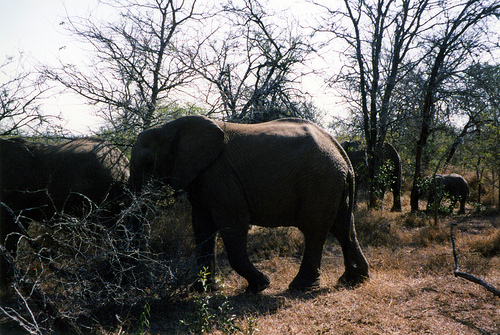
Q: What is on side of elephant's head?
A: Large ear.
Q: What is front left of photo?
A: Bare branches.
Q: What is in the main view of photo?
A: Elephant.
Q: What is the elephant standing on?
A: Patch of ground.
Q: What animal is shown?
A: Elephants.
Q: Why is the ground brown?
A: Dry.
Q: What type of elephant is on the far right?
A: Baby.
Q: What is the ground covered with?
A: Grass.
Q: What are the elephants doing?
A: Standing.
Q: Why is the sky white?
A: Cloudy.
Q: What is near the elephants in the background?
A: Trees.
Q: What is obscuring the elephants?
A: Trees.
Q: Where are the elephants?
A: Forest.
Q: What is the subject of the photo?
A: Elephant.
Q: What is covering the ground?
A: Dead grass.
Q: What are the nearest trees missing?
A: Leaves.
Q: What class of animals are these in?
A: Mammal.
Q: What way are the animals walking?
A: Left.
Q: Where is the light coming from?
A: Sun.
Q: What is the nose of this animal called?
A: Trunk.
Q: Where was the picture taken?
A: In the daytime.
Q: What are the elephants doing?
A: Walking.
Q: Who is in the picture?
A: Elephants.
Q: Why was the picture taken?
A: To capture the elephants.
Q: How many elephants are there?
A: 4.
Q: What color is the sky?
A: Gray.